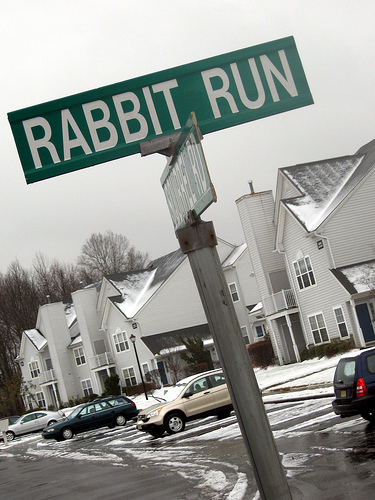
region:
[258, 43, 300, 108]
white letter on a sign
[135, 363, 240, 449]
car parked in a lot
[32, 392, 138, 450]
car parked in a lot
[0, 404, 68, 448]
car parked in a lot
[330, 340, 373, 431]
car parked in a lot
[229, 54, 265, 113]
white letter on a sign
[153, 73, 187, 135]
white letter on a sign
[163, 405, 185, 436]
tire and rim on a car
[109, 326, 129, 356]
window on a building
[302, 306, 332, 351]
window on a building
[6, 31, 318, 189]
slanted green street sign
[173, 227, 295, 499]
metal slanted sign pole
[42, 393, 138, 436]
dark colored station wagon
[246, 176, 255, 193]
vertical chimney exhaust pipe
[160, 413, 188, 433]
front rubber auto tire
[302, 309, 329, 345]
first story double window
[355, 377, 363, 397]
read rear brake light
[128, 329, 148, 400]
short street light pole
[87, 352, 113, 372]
second story balcony guard rail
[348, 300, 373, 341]
dark blue front door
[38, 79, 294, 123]
green street sign on pole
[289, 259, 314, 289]
windows on apartment building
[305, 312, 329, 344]
windows on apartment building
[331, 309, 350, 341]
windows on apartment building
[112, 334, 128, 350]
windows on apartment building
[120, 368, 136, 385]
windows on apartment building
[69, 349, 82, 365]
windows on apartment building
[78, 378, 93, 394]
windows on apartment building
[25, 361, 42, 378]
windows on apartment building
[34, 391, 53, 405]
windows on apartment building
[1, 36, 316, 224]
the green street signs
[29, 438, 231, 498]
the slushy snow on the ground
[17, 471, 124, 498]
the dark gray pavement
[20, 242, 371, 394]
the homes in a row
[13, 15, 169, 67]
the gray sky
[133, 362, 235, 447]
the parked gold car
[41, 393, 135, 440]
the parked station wagon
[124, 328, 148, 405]
the black street light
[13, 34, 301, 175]
the street sign that says RABBIT RUN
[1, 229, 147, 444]
the bare trees behind the houses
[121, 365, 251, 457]
a car parked in a parking lot.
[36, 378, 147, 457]
a car parked in front of a house.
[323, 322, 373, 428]
a car parked near a house.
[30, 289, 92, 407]
a large fireplace near a home.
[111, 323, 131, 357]
a second story window.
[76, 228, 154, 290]
a large leafless tree.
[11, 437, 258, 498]
tire tracks in snow.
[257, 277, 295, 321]
a balcony on a home.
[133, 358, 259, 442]
a parked brown car.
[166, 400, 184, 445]
a tire on a truck.